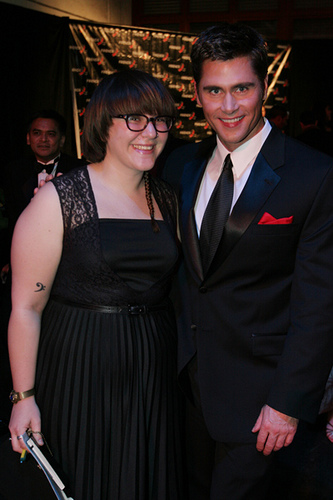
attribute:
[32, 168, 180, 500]
dress — black, formal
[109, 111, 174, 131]
glasses — black, brown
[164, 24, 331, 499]
man — smiling, young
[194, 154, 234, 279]
tie — black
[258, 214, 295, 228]
handkerchief — red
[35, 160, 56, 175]
bowtie — black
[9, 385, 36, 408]
bracelet — gold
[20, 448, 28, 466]
pen — ball point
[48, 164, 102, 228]
shoulder strap — black, lace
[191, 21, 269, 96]
brown hair — groomed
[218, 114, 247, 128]
lips — red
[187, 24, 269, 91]
hair — groomed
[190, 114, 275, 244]
shirt — white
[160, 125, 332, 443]
coat — black